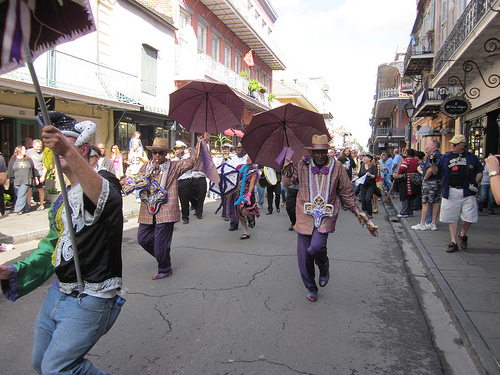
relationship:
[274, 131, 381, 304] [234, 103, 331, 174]
men carrying umbrella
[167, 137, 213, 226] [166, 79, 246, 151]
men carrying umbrella